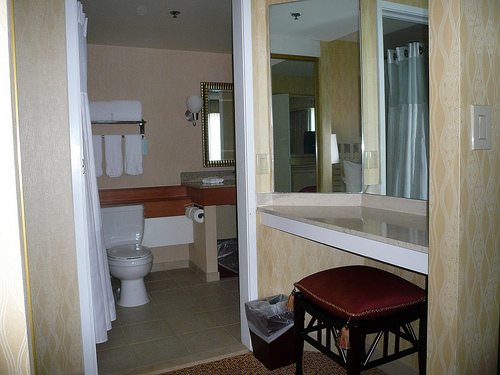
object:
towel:
[102, 133, 124, 179]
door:
[66, 0, 100, 375]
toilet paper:
[188, 206, 205, 224]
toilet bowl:
[103, 241, 155, 281]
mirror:
[266, 1, 362, 195]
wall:
[250, 1, 460, 374]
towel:
[90, 132, 105, 178]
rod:
[90, 132, 148, 140]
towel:
[122, 131, 145, 175]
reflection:
[268, 50, 320, 194]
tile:
[164, 310, 222, 335]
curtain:
[76, 1, 117, 344]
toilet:
[96, 203, 154, 308]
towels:
[86, 99, 143, 124]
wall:
[453, 0, 499, 374]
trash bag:
[243, 291, 298, 344]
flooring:
[174, 320, 222, 355]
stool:
[291, 289, 427, 374]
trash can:
[242, 292, 299, 372]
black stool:
[291, 291, 428, 374]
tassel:
[334, 312, 351, 350]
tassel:
[283, 285, 300, 313]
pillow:
[291, 263, 428, 322]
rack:
[90, 118, 147, 140]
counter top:
[256, 203, 427, 249]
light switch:
[467, 105, 493, 153]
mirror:
[198, 80, 236, 168]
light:
[182, 94, 208, 128]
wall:
[80, 43, 241, 280]